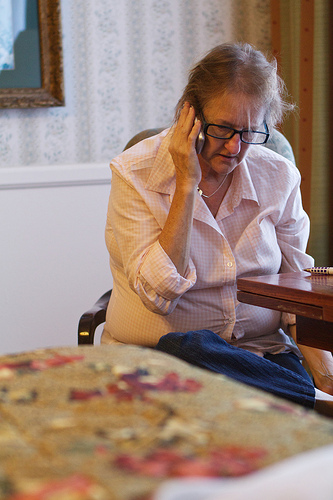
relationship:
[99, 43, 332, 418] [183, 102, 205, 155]
woman on phone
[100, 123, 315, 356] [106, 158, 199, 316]
shirt has sleeve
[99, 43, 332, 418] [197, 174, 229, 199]
woman has jewelry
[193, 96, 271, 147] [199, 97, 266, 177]
glasses on face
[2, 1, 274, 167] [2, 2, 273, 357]
wallpaper on wall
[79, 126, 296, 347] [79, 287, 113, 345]
chair has arm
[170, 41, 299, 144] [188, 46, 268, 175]
hair on head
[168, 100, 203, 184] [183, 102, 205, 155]
hand on phone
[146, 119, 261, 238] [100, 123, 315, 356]
collar on shirt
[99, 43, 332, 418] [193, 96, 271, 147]
woman wearing glasses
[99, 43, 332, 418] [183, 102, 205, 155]
woman talking on phone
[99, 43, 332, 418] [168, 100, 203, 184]
woman has hand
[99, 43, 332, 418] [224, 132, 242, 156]
woman has nose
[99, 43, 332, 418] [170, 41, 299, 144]
woman has hair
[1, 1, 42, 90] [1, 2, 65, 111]
picture in frame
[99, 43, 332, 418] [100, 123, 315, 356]
woman wearing shirt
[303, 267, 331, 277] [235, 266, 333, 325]
fountain pen on table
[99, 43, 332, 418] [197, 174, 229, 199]
woman wearing jewelry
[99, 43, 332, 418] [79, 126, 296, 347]
woman sitting on chair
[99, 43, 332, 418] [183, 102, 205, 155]
woman holding phone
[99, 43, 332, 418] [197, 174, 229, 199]
woman with jewelry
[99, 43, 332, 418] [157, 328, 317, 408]
woman wearing pants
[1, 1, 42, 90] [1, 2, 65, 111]
picture has frame